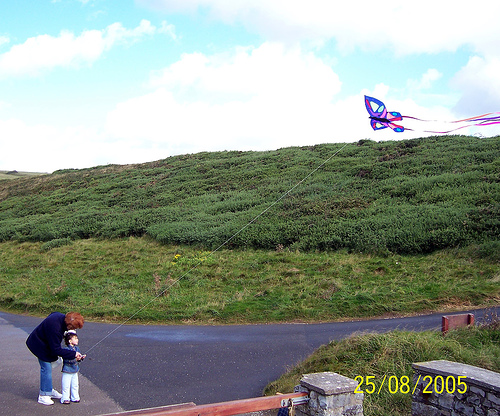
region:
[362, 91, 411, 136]
colorful butterfly kite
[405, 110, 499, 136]
multi colored tail of a kite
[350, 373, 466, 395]
timestamp showing what day it was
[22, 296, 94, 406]
mother with son flying a kite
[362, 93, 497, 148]
colorful kite in the sky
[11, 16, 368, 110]
fluffy white clouds in bright blue sky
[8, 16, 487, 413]
scene of a mother teaching her son to fly a kite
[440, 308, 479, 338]
red wooden sign in a patch of grass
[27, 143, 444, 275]
large hill covered in vegetative growth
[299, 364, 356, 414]
stone structure supporting a fence railing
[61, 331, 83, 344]
the head of a child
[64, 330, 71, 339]
the hair of a child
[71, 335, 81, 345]
the face of a child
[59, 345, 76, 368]
the torso of a child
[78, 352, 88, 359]
the hand of a child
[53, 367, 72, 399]
the right leg of a child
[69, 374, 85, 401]
the left leg of a child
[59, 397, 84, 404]
the shoes of a child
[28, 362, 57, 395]
the leg of a woman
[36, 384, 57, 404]
the shoes of a woman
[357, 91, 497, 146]
Butterfly kite with long tail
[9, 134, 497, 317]
Green hill with long grass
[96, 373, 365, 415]
Rock wall with wood gate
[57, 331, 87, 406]
Child with dark hair wearing white pants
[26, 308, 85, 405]
Woman wearing blue coat and jeans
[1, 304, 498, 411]
Dark paved road beside grass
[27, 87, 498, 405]
Child holding on to kite string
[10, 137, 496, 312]
Few yellow flowers in green field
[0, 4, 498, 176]
Blue sky with many white clouds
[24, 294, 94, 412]
a woman with her child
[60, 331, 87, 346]
the head of a child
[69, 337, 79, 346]
the face of a child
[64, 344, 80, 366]
the torso of a child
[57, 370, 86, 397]
the pants of a child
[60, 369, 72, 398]
the right leg of a child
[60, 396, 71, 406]
the right foot of a child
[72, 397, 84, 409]
the left foot of a child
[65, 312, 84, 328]
the hair of a woman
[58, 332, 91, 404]
little boy flying kite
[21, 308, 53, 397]
mom with little boy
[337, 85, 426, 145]
butterfly kite in sky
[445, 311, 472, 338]
brick wall in ground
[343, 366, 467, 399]
date in the corner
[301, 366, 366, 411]
brick column in corner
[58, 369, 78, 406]
white pants on child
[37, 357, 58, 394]
jeans on the mom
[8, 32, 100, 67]
fluffy clouds in the sky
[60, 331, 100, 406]
a young child holding a kite string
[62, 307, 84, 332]
a woman with red hair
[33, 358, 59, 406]
a woman wearing blue jeans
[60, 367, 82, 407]
a young child wearing white pants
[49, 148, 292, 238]
a hillside covered with green grass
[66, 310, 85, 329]
the head of a woman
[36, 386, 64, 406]
the feet of a woman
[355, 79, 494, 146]
a kite being flown by a child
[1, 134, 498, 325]
a large green field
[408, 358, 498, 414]
a stone wall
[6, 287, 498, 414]
a roadway where the woman and child is standing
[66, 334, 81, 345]
the childs head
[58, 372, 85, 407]
the childs white pants